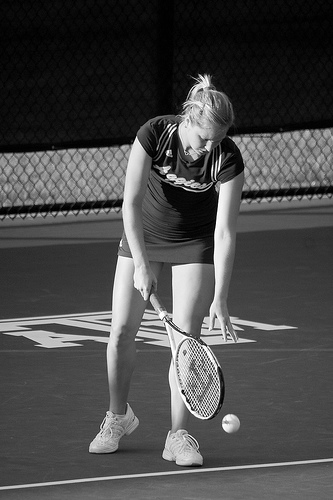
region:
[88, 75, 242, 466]
woman playing tennis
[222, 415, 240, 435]
tennis ball off the ground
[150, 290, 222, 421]
tennis racket in the woman's hand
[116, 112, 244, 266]
tennis outfit on the woman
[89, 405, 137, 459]
white shoe on the woman's right foot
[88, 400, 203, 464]
white tennis shoes on the woman's feet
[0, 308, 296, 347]
painted symbol on the ground of the court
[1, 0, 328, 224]
fence behind the tennis court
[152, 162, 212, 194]
name on the woman's shirt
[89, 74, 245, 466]
the woman is looking at the ball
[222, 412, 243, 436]
a tennis ball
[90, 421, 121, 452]
white shoes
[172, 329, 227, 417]
a tennis racket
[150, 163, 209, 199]
logo on the jersey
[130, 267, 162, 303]
tennis player holding tennis racket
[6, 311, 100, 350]
logo on tennis court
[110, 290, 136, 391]
the womens leg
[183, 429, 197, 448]
shoe laces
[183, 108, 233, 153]
the women is looking down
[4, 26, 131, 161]
a fence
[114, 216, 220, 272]
the girl is wearing a skirt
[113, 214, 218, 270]
the skirt is short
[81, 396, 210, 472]
the girl is wearing tennis shoes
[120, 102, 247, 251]
the girl is wearing a dark top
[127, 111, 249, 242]
the girl's top is short sleeved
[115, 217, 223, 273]
the girl's skirt is too tight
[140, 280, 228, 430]
the girl is holding a racket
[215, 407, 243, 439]
the girl is bouncing the ball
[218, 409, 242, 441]
the ball is a tennis ball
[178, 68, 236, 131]
the girl's hair is in a pony tail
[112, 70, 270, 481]
a woman playing tennis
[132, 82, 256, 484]
a woman preparing to serve the ball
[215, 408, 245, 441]
a ball used to play tennis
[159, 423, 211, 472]
a white tennis shoe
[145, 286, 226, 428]
a racket used to play tennis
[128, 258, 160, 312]
a forehand grip on a tennis racket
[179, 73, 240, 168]
a woman with blonde hair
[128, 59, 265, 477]
a woman bouncing a tennis ball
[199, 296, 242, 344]
a woman's hand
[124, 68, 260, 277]
a woman wearing a tennis outfit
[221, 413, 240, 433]
the ball in mid air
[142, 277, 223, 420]
the tennis racquet in the woman's hand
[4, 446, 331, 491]
the line on the ground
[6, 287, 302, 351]
the white letters on the ground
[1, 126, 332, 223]
the bottom of the fence behind the woman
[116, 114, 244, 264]
the woman's tennis outfit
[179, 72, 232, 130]
the hair on the woman's head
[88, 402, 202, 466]
the pair of shoes on the woman's feet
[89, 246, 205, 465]
the woman's two legs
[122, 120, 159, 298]
the woman's right arm